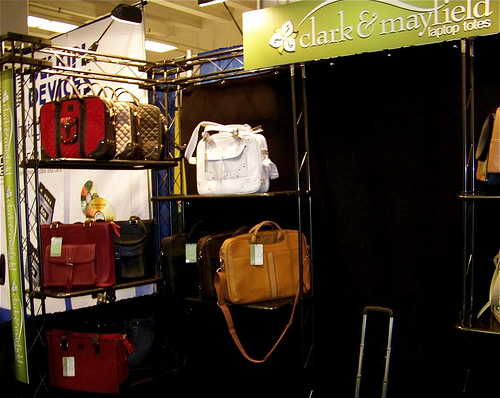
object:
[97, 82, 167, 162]
bag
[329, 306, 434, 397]
bag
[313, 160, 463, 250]
ground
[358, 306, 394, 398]
handle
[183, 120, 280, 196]
bag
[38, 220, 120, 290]
bag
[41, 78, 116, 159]
bag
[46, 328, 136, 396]
bag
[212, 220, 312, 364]
bag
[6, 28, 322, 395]
hanging shelves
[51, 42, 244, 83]
silver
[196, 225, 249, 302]
bag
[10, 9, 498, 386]
store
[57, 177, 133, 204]
board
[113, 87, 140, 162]
bags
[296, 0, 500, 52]
letters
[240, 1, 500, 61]
sign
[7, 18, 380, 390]
display